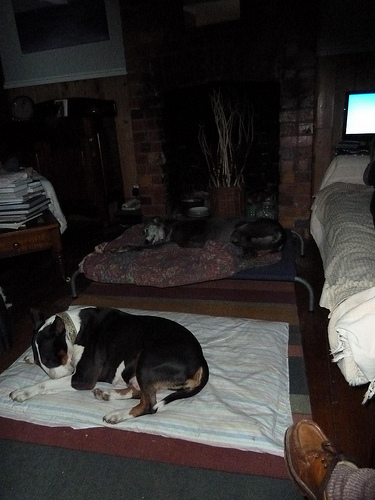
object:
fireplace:
[154, 30, 279, 217]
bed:
[309, 157, 375, 404]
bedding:
[319, 181, 372, 332]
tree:
[199, 93, 254, 187]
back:
[103, 363, 162, 424]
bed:
[0, 278, 313, 499]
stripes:
[26, 427, 208, 499]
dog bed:
[78, 222, 296, 288]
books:
[0, 167, 52, 229]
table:
[0, 209, 68, 295]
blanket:
[0, 307, 293, 458]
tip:
[153, 399, 168, 414]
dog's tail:
[152, 360, 209, 411]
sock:
[327, 461, 375, 499]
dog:
[9, 304, 209, 424]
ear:
[53, 315, 65, 334]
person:
[284, 418, 374, 499]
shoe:
[284, 417, 346, 500]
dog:
[143, 215, 286, 258]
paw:
[9, 388, 33, 402]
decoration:
[196, 87, 254, 215]